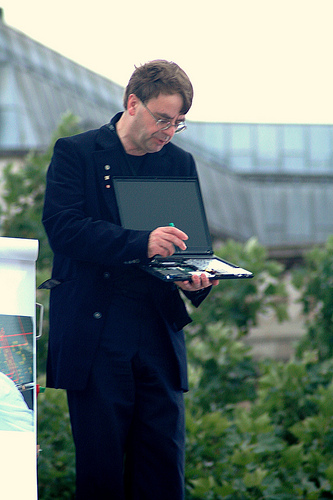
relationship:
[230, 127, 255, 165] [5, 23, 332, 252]
glass panel on structure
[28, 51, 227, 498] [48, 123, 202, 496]
man in suit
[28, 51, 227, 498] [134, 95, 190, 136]
man has glasses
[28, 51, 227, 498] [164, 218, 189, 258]
man has tool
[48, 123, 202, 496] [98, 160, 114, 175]
suit has pin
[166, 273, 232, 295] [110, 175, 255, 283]
hand under laptop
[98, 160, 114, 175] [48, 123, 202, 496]
pin on suit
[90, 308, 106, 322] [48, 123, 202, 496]
pin on suit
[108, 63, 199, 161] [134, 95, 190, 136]
face has glasses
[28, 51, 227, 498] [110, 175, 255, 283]
man working on laptop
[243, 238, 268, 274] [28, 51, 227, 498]
leaves behind man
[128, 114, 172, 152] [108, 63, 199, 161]
five o'clock shadow on face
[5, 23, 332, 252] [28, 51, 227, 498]
structure behind man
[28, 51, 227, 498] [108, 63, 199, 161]
man has face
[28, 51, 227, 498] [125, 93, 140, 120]
man has ear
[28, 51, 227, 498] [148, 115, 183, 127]
man has eyes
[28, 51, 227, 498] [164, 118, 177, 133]
man has nose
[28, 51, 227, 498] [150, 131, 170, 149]
man has mouth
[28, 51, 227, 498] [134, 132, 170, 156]
man has chin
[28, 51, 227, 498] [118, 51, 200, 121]
man has hair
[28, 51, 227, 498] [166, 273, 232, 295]
man has hand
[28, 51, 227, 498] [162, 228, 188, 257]
man has fingers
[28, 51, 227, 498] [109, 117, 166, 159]
man has neck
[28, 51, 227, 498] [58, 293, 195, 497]
man has pants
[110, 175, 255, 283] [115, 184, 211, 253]
laptop has screen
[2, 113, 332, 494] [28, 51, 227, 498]
trees behind man